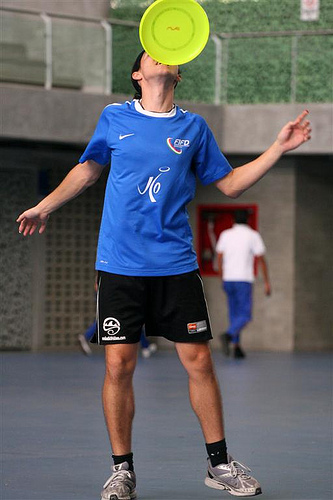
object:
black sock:
[206, 437, 229, 468]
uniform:
[81, 98, 230, 342]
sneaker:
[206, 461, 265, 496]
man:
[214, 208, 274, 364]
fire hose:
[196, 205, 257, 276]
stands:
[46, 173, 115, 363]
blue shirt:
[79, 101, 233, 275]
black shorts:
[90, 268, 214, 345]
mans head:
[133, 44, 180, 112]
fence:
[3, 9, 333, 107]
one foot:
[219, 285, 254, 357]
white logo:
[101, 317, 126, 341]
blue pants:
[222, 280, 254, 338]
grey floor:
[0, 354, 333, 499]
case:
[196, 203, 261, 281]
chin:
[144, 141, 179, 156]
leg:
[176, 276, 263, 499]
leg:
[99, 274, 140, 500]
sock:
[111, 452, 134, 470]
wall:
[2, 82, 332, 155]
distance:
[3, 79, 333, 352]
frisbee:
[141, 0, 211, 68]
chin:
[145, 65, 178, 81]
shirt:
[214, 220, 267, 282]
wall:
[1, 136, 333, 353]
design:
[136, 166, 172, 203]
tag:
[186, 320, 206, 334]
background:
[0, 138, 331, 357]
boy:
[17, 46, 314, 498]